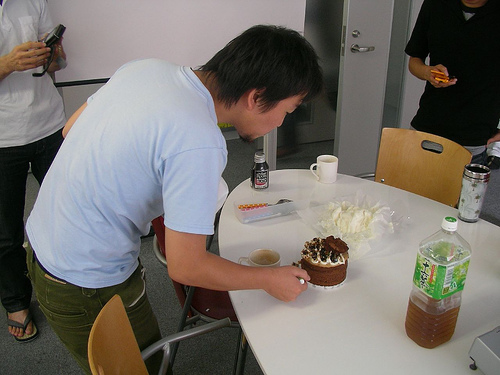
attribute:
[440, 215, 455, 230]
top — green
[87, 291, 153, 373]
chair — yellow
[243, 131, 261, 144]
beard — short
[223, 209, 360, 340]
strap — small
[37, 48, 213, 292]
shirt — white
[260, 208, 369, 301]
chocolate cake — small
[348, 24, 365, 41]
lock — steel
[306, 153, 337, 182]
cup — white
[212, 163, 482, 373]
table — white